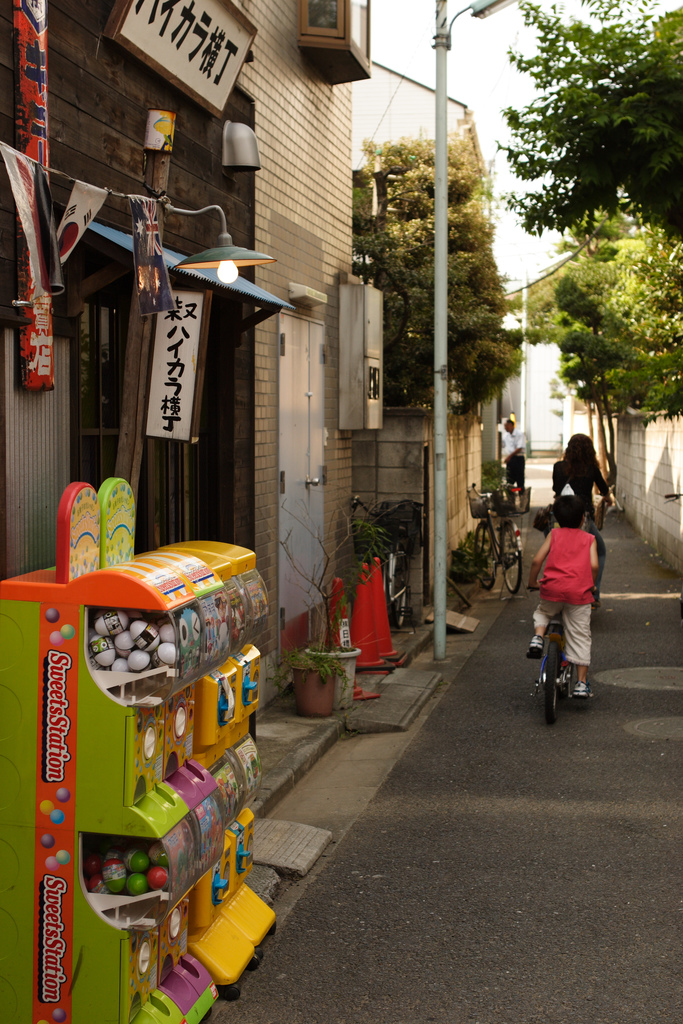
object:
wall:
[232, 2, 354, 698]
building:
[0, 0, 369, 723]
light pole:
[433, 0, 449, 663]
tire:
[545, 639, 559, 723]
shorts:
[532, 600, 592, 667]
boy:
[529, 495, 600, 700]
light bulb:
[216, 259, 238, 283]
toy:
[88, 610, 177, 672]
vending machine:
[1, 477, 273, 1023]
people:
[525, 435, 615, 723]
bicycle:
[531, 613, 572, 724]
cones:
[325, 577, 363, 696]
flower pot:
[305, 647, 362, 711]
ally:
[201, 503, 682, 1018]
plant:
[258, 485, 399, 651]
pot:
[290, 656, 337, 716]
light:
[599, 592, 682, 600]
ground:
[211, 507, 681, 1024]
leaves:
[399, 224, 426, 269]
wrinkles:
[539, 561, 577, 588]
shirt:
[538, 528, 596, 605]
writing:
[45, 649, 71, 783]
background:
[32, 600, 78, 1024]